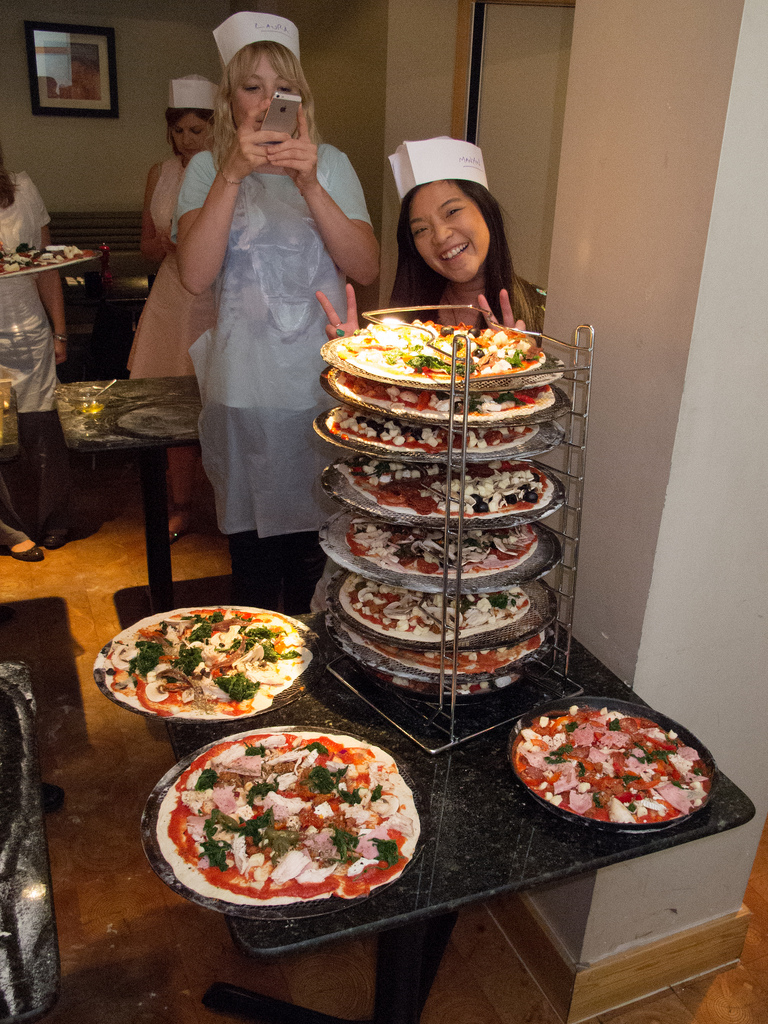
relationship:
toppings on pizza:
[213, 761, 372, 858] [184, 758, 397, 876]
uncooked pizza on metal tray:
[99, 594, 292, 704] [89, 635, 313, 723]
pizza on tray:
[500, 692, 709, 829] [530, 681, 729, 841]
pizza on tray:
[335, 335, 557, 396] [335, 335, 550, 396]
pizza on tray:
[317, 373, 560, 438] [317, 373, 560, 438]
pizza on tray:
[323, 411, 556, 474] [323, 411, 556, 474]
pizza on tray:
[329, 466, 559, 526] [329, 466, 559, 526]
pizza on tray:
[333, 521, 568, 590] [333, 521, 568, 590]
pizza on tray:
[333, 578, 555, 654] [333, 578, 555, 654]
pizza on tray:
[365, 644, 598, 698] [365, 644, 598, 698]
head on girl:
[378, 137, 506, 292] [378, 137, 528, 297]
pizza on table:
[139, 748, 434, 908] [152, 606, 699, 907]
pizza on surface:
[184, 757, 397, 875] [184, 598, 496, 875]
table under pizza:
[178, 680, 514, 891] [178, 732, 409, 891]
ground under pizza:
[55, 842, 158, 958] [148, 727, 442, 904]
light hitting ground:
[48, 657, 147, 927] [48, 657, 147, 927]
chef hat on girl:
[384, 132, 499, 201] [378, 141, 516, 296]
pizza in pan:
[500, 691, 709, 828] [516, 698, 710, 827]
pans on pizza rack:
[317, 298, 580, 708] [311, 306, 597, 686]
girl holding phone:
[206, 25, 340, 176] [261, 86, 311, 164]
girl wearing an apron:
[206, 25, 340, 176] [200, 162, 337, 452]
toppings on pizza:
[162, 626, 265, 687] [157, 728, 420, 899]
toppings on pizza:
[230, 769, 367, 863] [517, 695, 707, 822]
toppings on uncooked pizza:
[575, 731, 663, 792] [99, 594, 292, 704]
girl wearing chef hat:
[311, 130, 555, 369] [384, 132, 499, 201]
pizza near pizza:
[184, 758, 397, 876] [500, 691, 709, 828]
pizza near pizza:
[500, 691, 709, 828] [184, 758, 397, 876]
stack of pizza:
[318, 293, 573, 739] [336, 639, 576, 687]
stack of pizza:
[318, 293, 573, 739] [350, 587, 531, 631]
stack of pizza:
[318, 293, 573, 739] [375, 532, 542, 580]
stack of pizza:
[318, 293, 573, 739] [323, 411, 552, 461]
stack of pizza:
[318, 293, 573, 739] [322, 314, 545, 385]